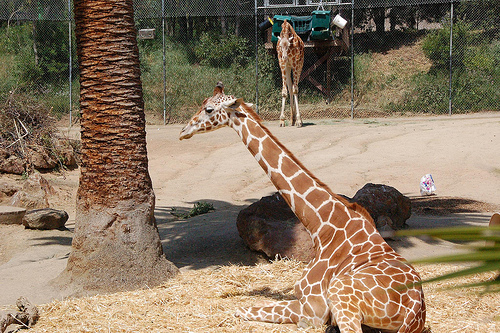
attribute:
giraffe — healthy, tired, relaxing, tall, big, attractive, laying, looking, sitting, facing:
[176, 78, 433, 326]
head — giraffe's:
[173, 78, 246, 140]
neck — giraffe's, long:
[233, 108, 357, 240]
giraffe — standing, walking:
[273, 18, 312, 129]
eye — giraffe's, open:
[206, 102, 217, 116]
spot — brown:
[260, 134, 283, 174]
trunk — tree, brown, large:
[57, 2, 173, 293]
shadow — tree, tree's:
[39, 183, 494, 305]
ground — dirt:
[13, 110, 497, 318]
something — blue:
[267, 4, 334, 49]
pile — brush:
[0, 5, 86, 176]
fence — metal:
[2, 1, 500, 127]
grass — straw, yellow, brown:
[43, 212, 500, 323]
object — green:
[272, 6, 333, 41]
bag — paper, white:
[422, 177, 438, 196]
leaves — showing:
[337, 13, 496, 112]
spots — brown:
[232, 116, 411, 316]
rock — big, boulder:
[232, 182, 370, 267]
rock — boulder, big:
[342, 181, 415, 237]